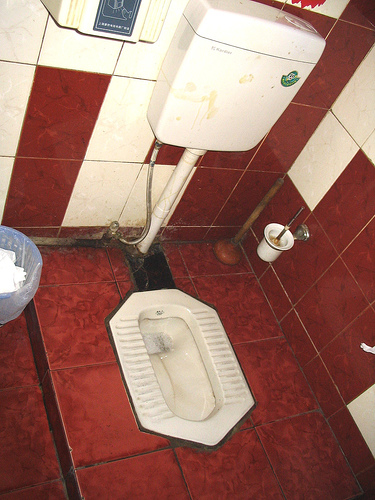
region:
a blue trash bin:
[2, 211, 56, 336]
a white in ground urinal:
[97, 271, 267, 459]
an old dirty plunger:
[203, 169, 307, 280]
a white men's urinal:
[95, 273, 277, 459]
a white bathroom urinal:
[116, 2, 315, 458]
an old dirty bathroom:
[5, 1, 374, 445]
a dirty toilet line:
[97, 125, 173, 260]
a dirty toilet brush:
[247, 189, 320, 276]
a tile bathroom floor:
[3, 187, 373, 485]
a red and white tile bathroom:
[6, 103, 370, 486]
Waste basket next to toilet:
[0, 215, 56, 330]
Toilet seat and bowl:
[92, 271, 261, 471]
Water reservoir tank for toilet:
[143, 0, 328, 180]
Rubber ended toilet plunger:
[206, 192, 256, 268]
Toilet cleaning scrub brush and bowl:
[247, 195, 322, 265]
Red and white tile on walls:
[306, 120, 369, 261]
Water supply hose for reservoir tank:
[117, 139, 156, 254]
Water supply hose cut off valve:
[98, 217, 121, 242]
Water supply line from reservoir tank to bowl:
[152, 142, 208, 252]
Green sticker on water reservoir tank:
[272, 62, 302, 92]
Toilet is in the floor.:
[105, 283, 262, 452]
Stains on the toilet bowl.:
[193, 92, 228, 130]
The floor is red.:
[270, 441, 330, 468]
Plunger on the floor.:
[212, 228, 255, 269]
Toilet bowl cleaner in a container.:
[257, 222, 299, 254]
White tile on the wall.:
[318, 105, 368, 137]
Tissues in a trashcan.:
[0, 256, 36, 284]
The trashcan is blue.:
[12, 235, 42, 258]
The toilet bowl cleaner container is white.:
[260, 240, 291, 258]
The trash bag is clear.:
[0, 291, 38, 323]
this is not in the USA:
[12, 153, 283, 498]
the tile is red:
[12, 330, 118, 486]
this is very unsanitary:
[99, 1, 325, 284]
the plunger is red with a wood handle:
[210, 161, 267, 277]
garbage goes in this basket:
[0, 215, 60, 336]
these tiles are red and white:
[10, 61, 131, 218]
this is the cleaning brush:
[254, 198, 312, 264]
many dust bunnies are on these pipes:
[51, 210, 199, 286]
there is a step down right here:
[12, 321, 112, 486]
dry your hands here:
[42, 0, 181, 51]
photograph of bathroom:
[38, 16, 357, 414]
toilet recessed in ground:
[99, 279, 261, 461]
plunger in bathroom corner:
[210, 173, 297, 271]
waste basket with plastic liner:
[8, 200, 48, 315]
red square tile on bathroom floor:
[36, 344, 133, 467]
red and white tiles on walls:
[38, 82, 143, 211]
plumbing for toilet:
[105, 150, 215, 264]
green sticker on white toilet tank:
[271, 71, 310, 95]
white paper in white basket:
[0, 237, 46, 297]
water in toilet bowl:
[149, 328, 175, 357]